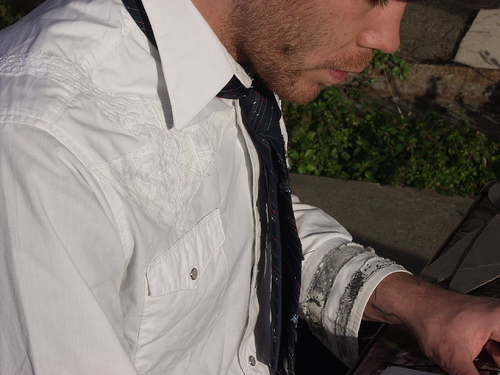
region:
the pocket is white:
[157, 320, 172, 345]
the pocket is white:
[200, 298, 212, 329]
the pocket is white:
[151, 328, 183, 361]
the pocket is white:
[167, 318, 179, 331]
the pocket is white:
[179, 335, 186, 343]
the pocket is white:
[146, 325, 170, 337]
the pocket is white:
[152, 329, 174, 346]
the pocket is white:
[164, 313, 176, 338]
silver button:
[185, 266, 200, 281]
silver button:
[182, 265, 197, 286]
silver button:
[190, 260, 222, 297]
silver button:
[179, 255, 213, 291]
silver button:
[183, 257, 200, 292]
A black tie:
[265, 227, 311, 370]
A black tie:
[235, 190, 291, 322]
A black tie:
[215, 110, 293, 315]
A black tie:
[217, 84, 342, 366]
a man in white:
[104, 234, 154, 274]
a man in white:
[106, 123, 208, 267]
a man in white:
[114, 161, 172, 228]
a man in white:
[165, 167, 278, 368]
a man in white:
[151, 191, 183, 233]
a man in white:
[127, 200, 219, 318]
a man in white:
[163, 260, 222, 335]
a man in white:
[49, 119, 165, 256]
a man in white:
[56, 63, 213, 247]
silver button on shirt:
[174, 261, 212, 303]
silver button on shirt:
[187, 267, 234, 312]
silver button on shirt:
[180, 241, 225, 316]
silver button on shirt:
[178, 257, 195, 291]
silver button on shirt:
[168, 250, 248, 332]